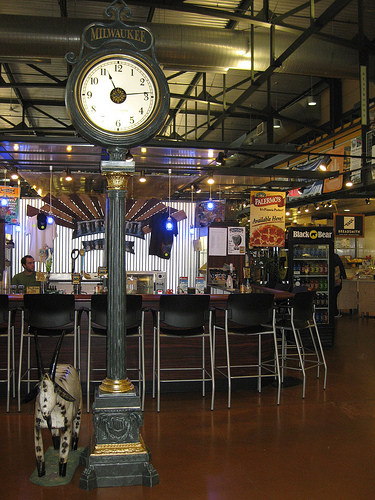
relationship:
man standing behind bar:
[13, 255, 48, 294] [0, 276, 296, 400]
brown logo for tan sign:
[29, 191, 187, 240] [36, 190, 187, 236]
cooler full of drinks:
[281, 225, 336, 351] [294, 246, 327, 321]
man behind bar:
[12, 255, 41, 294] [4, 289, 292, 382]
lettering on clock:
[92, 26, 142, 44] [64, 22, 172, 149]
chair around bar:
[279, 291, 328, 395] [34, 282, 290, 320]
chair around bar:
[215, 287, 280, 403] [34, 282, 290, 320]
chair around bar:
[150, 287, 219, 414] [34, 282, 290, 320]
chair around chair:
[76, 288, 152, 417] [18, 283, 84, 404]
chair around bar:
[18, 283, 84, 404] [34, 282, 290, 320]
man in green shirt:
[12, 255, 41, 294] [9, 269, 44, 286]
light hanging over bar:
[200, 188, 224, 216] [41, 197, 61, 224]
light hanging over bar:
[166, 221, 173, 230] [41, 197, 61, 224]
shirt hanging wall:
[25, 213, 57, 262] [11, 195, 198, 290]